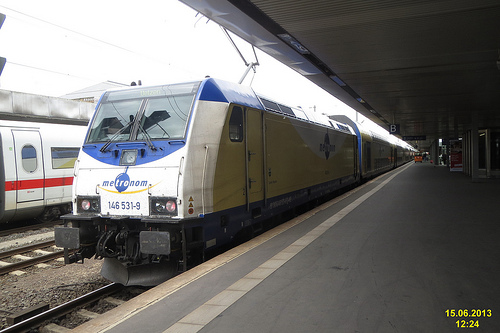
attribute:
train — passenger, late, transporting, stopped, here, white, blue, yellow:
[71, 95, 360, 217]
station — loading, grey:
[397, 195, 431, 220]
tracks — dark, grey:
[38, 278, 114, 306]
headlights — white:
[149, 195, 179, 219]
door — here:
[258, 136, 279, 204]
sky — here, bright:
[140, 13, 159, 20]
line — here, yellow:
[299, 222, 336, 240]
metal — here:
[220, 5, 244, 20]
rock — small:
[36, 273, 53, 279]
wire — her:
[60, 21, 91, 61]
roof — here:
[233, 91, 304, 107]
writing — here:
[114, 182, 138, 191]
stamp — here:
[428, 303, 488, 330]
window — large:
[317, 131, 346, 153]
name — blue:
[309, 143, 337, 160]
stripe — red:
[28, 180, 76, 191]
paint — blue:
[186, 75, 227, 105]